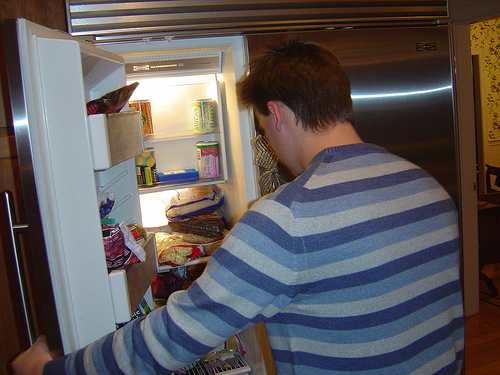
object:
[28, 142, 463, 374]
sweater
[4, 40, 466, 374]
boy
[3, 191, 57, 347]
handle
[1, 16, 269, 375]
fridge door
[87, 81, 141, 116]
pack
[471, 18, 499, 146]
wall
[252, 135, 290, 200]
ribbon